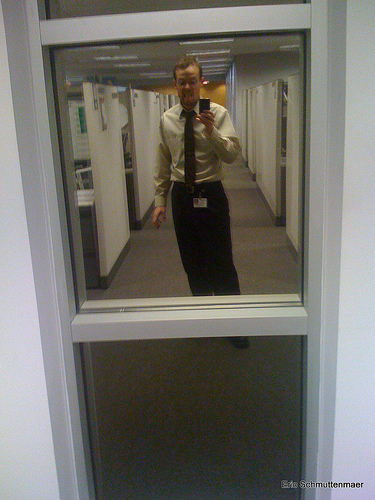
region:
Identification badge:
[187, 189, 211, 210]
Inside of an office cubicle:
[53, 76, 118, 294]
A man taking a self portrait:
[145, 49, 260, 355]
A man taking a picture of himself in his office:
[139, 46, 283, 370]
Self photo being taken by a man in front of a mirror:
[133, 53, 274, 365]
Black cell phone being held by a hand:
[192, 95, 218, 127]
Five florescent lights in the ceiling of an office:
[65, 40, 175, 85]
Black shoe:
[217, 323, 256, 355]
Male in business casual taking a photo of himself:
[142, 50, 268, 368]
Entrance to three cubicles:
[240, 70, 309, 258]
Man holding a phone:
[129, 46, 274, 259]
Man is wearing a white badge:
[183, 186, 216, 217]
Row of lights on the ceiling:
[91, 23, 289, 91]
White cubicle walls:
[81, 78, 163, 299]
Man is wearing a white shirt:
[130, 58, 252, 209]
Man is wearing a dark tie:
[174, 104, 208, 205]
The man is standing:
[99, 50, 300, 351]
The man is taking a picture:
[145, 50, 269, 352]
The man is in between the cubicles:
[95, 54, 305, 302]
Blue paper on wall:
[68, 96, 99, 147]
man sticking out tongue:
[134, 52, 259, 371]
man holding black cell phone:
[126, 49, 275, 372]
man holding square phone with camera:
[129, 51, 272, 374]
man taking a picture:
[123, 50, 269, 371]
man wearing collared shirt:
[137, 45, 265, 359]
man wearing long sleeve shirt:
[125, 49, 279, 370]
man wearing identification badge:
[129, 48, 278, 378]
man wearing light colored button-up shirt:
[130, 50, 278, 368]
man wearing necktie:
[124, 46, 280, 380]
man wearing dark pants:
[116, 55, 274, 363]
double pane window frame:
[54, 300, 322, 345]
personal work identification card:
[184, 191, 214, 212]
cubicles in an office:
[72, 80, 193, 295]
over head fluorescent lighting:
[80, 53, 177, 81]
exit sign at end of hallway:
[197, 77, 212, 87]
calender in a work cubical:
[63, 94, 99, 162]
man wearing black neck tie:
[175, 104, 199, 191]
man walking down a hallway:
[140, 54, 268, 353]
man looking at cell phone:
[172, 58, 230, 131]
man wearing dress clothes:
[149, 51, 252, 361]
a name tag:
[190, 196, 211, 209]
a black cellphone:
[196, 96, 212, 113]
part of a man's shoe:
[228, 336, 249, 347]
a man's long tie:
[178, 110, 195, 186]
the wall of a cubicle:
[82, 84, 132, 289]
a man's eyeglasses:
[174, 78, 200, 87]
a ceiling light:
[92, 53, 140, 64]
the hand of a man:
[151, 203, 168, 230]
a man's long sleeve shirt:
[155, 99, 242, 207]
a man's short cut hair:
[171, 54, 204, 80]